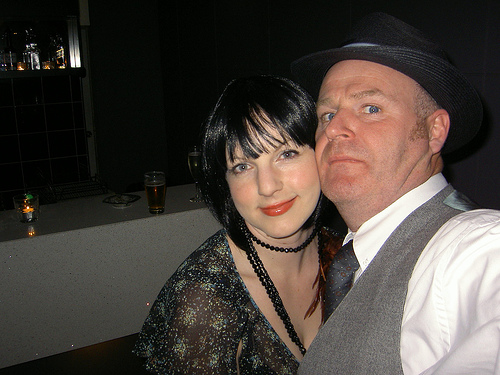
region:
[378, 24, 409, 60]
Small part of the man's black hat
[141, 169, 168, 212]
Glass that is filled with a drink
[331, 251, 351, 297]
Black and orange tie of the male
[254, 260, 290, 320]
Black beeded necklace of the women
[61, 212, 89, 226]
Gray table in the room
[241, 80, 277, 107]
Black hair of the female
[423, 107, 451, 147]
Left ear of the man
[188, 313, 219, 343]
Clear black shirt of the woman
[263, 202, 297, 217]
Lipstick on the woman's lips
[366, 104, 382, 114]
Left blue eyes of the man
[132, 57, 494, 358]
A man and woman posing for a picture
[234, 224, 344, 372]
a black beaded necklace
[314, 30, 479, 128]
black hat on man's head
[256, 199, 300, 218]
woman has orange lipstick on lips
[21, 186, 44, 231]
a candle is buring on the counter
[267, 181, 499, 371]
a gray vest worn by the man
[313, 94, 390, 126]
Blue eyes of a man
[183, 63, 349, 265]
The woman has black hair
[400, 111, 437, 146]
short sideburn on the man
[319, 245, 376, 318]
the man wears a necktie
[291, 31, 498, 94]
Black hut on a man's head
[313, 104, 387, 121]
A man's clear eyes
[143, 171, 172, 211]
A glass of beer on a table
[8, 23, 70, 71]
Beer rank with all types of beers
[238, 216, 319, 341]
A Beautiful black necklace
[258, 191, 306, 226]
Nicely Polished lips with lipstick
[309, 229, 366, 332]
A well tied grey tie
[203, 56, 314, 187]
well plaited fringe weaves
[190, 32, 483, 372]
couple possing for a photo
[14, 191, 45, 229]
A glass of beer halfway full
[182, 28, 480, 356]
couple posing for photo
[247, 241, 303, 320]
black necklace on woman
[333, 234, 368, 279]
tie on man's neck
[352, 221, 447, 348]
gray vest on white shirt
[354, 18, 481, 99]
black hat on head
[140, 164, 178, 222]
glass of beer on table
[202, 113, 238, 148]
light reflection on black hair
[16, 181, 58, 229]
glowing candle in glass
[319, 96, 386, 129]
blue eyes on man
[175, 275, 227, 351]
print on woman's top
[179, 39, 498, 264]
man and woman close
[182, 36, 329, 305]
woman wearing red lipstick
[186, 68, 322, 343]
woman wearing black necklace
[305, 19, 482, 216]
man wearing black hat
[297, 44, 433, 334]
man wearing black tie with red specks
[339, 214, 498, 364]
gray vest and white shirt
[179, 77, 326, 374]
black and blue top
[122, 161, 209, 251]
drink on counter top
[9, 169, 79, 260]
lit candle on counter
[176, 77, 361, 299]
woman has black hair